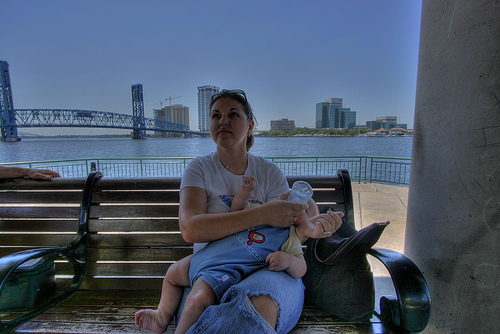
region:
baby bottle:
[284, 179, 314, 211]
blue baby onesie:
[186, 207, 293, 297]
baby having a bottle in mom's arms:
[133, 180, 317, 330]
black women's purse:
[297, 215, 390, 323]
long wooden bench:
[2, 170, 433, 332]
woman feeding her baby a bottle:
[132, 87, 345, 332]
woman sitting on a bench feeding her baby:
[2, 87, 432, 332]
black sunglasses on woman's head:
[207, 87, 250, 117]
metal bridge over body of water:
[0, 56, 210, 139]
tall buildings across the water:
[312, 94, 359, 134]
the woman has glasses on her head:
[207, 87, 249, 103]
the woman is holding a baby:
[142, 100, 345, 329]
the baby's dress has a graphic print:
[235, 228, 267, 256]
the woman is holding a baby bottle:
[285, 179, 312, 206]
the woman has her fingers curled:
[305, 208, 345, 238]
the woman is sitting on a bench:
[2, 165, 429, 332]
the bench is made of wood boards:
[89, 179, 339, 289]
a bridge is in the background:
[2, 58, 213, 153]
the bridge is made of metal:
[2, 60, 202, 141]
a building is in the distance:
[313, 94, 355, 127]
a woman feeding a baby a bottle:
[181, 103, 313, 332]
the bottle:
[290, 180, 317, 211]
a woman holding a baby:
[183, 90, 321, 332]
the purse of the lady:
[300, 211, 388, 322]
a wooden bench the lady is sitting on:
[18, 178, 407, 332]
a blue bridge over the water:
[6, 65, 195, 138]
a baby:
[145, 206, 310, 326]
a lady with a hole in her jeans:
[180, 86, 303, 332]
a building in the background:
[313, 96, 363, 126]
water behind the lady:
[38, 135, 406, 170]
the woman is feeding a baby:
[137, 92, 345, 332]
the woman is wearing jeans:
[178, 240, 305, 330]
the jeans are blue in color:
[186, 258, 306, 328]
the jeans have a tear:
[244, 288, 284, 333]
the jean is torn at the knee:
[246, 288, 284, 332]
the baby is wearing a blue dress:
[185, 212, 288, 284]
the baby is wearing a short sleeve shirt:
[241, 199, 301, 255]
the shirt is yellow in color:
[244, 198, 304, 259]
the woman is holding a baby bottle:
[272, 178, 314, 227]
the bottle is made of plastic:
[285, 181, 314, 205]